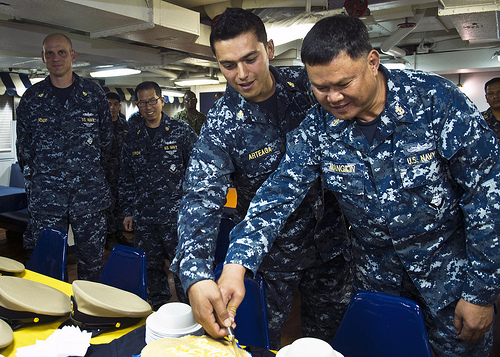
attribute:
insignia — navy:
[389, 96, 409, 119]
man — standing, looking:
[127, 81, 194, 229]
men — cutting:
[200, 7, 448, 288]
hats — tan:
[58, 261, 131, 339]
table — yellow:
[113, 335, 141, 356]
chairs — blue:
[346, 293, 422, 352]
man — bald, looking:
[13, 35, 137, 235]